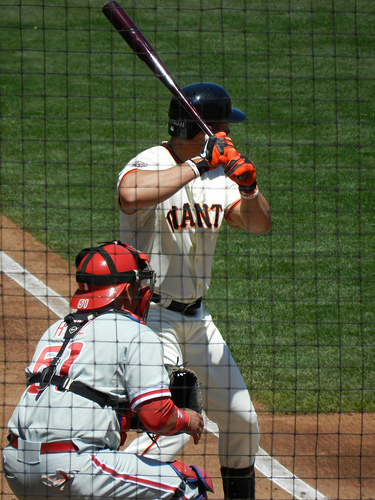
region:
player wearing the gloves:
[180, 123, 271, 213]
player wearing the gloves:
[186, 127, 295, 230]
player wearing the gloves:
[192, 130, 263, 211]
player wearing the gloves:
[187, 118, 251, 198]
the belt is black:
[151, 288, 211, 322]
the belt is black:
[146, 286, 214, 328]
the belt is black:
[143, 286, 213, 322]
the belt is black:
[148, 287, 205, 320]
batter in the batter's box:
[119, 83, 268, 498]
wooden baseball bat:
[102, 0, 246, 181]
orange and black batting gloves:
[190, 131, 254, 193]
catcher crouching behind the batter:
[1, 240, 214, 498]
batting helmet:
[168, 81, 243, 136]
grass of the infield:
[0, 0, 373, 408]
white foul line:
[0, 249, 324, 499]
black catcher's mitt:
[164, 358, 204, 414]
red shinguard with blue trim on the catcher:
[166, 458, 211, 497]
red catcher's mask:
[117, 240, 153, 323]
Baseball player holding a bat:
[91, 0, 277, 498]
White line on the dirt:
[0, 245, 326, 495]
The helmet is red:
[62, 236, 148, 307]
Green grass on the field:
[1, 1, 372, 415]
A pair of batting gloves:
[182, 127, 261, 202]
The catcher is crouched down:
[3, 235, 217, 498]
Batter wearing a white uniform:
[112, 75, 274, 497]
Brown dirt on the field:
[1, 208, 372, 498]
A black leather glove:
[163, 359, 209, 413]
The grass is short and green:
[279, 26, 365, 285]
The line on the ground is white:
[8, 240, 62, 333]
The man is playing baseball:
[81, 40, 302, 497]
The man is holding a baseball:
[97, 1, 253, 192]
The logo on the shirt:
[163, 189, 229, 238]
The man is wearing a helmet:
[57, 234, 162, 315]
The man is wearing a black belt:
[152, 290, 209, 322]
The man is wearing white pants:
[144, 302, 262, 472]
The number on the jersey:
[23, 338, 85, 398]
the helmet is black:
[162, 73, 246, 161]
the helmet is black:
[157, 70, 245, 136]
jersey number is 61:
[19, 316, 90, 397]